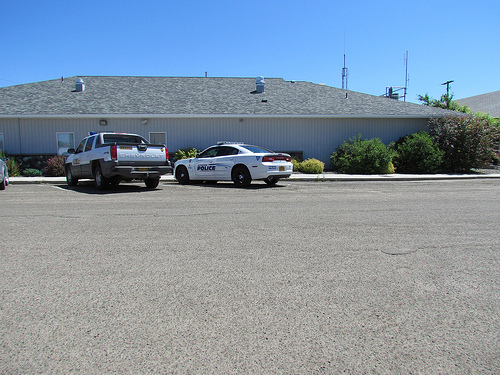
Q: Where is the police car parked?
A: In the lot.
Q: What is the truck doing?
A: Sitting.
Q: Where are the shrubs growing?
A: By the building.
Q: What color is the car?
A: White.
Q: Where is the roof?
A: On building.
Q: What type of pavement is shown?
A: Road.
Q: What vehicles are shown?
A: Cars.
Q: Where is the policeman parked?
A: Next to the truck.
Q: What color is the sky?
A: Blue.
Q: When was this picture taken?
A: During the day.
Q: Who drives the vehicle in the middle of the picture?
A: A police officer.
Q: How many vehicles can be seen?
A: Two.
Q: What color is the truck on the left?
A: Silver.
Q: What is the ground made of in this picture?
A: Asphalt.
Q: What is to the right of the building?
A: Shrubs.